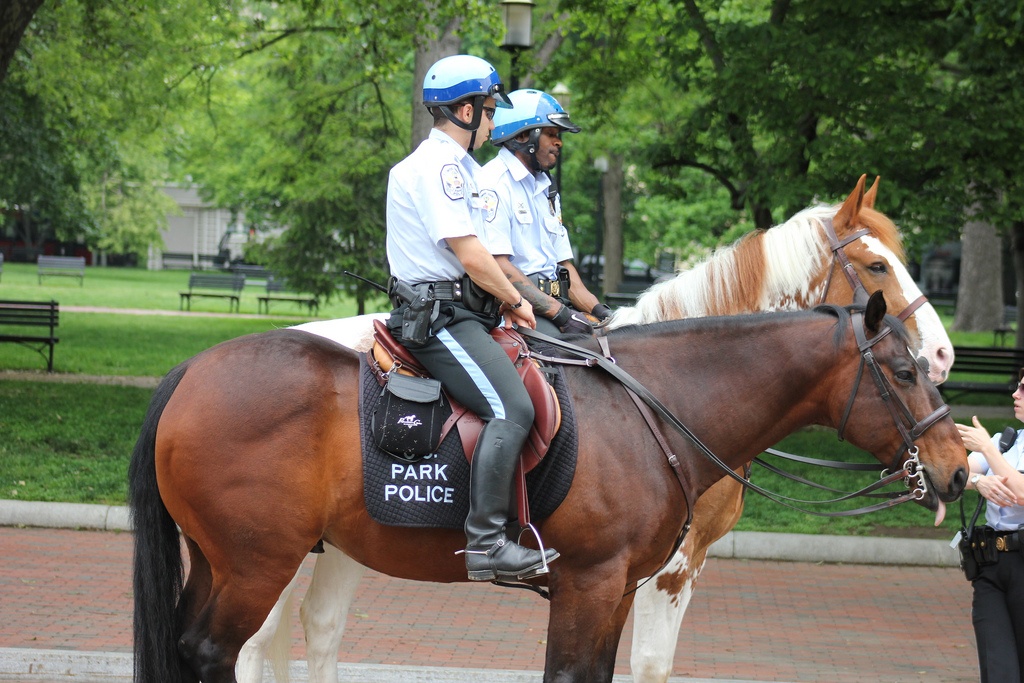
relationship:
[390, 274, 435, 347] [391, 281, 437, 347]
gun in gun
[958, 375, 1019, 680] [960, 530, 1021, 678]
woman wearing pants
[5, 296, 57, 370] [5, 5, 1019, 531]
bench in park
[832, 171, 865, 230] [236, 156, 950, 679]
ear. of horse